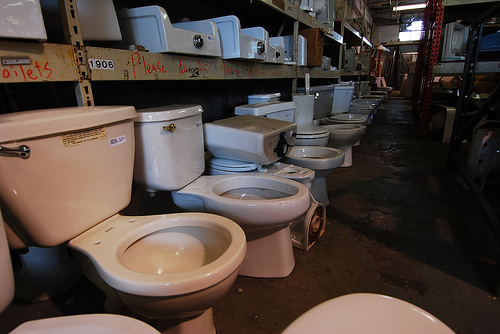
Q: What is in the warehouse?
A: Toilets.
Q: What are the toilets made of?
A: Porcelain.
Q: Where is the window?
A: On the back wall.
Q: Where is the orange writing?
A: On the shelves.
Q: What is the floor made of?
A: Concrete.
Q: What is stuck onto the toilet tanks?
A: Stickers.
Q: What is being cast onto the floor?
A: Shadows.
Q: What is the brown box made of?
A: Cardboard.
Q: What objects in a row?
A: Toilets.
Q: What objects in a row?
A: Toilets.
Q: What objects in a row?
A: Toilets.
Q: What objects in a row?
A: Toilets.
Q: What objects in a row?
A: Toilets.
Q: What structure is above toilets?
A: Shelf.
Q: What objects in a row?
A: Toilets.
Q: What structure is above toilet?
A: Shelf.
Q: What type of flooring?
A: Concrete.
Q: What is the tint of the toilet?
A: White.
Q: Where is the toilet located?
A: In a warehouse.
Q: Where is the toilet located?
A: In a warehouse.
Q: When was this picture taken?
A: It was taken in the day time.